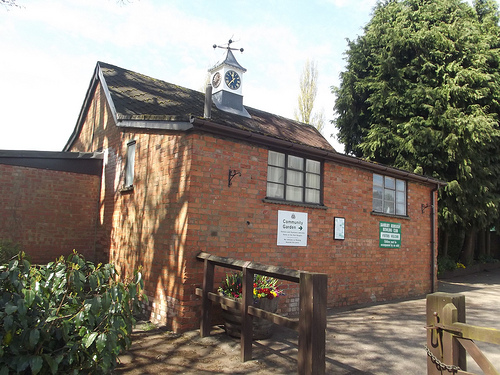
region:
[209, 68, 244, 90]
clock on two sides of tower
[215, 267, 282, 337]
bucket of red and yellow flowers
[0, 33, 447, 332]
a brick building with clock tower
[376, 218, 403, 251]
green and white sign on side of building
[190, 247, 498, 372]
an open wooden gate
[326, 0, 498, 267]
a large leaf covered tree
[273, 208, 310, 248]
a large white sign on side of building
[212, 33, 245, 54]
the weather vane on top of clock tower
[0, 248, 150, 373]
a large green bush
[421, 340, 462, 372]
a chain on the door of the fencec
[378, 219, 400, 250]
green sign with white writing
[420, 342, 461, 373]
chain around fence post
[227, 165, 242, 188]
metal hanger attached to building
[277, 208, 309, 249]
white sign with dark writing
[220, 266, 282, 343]
flowers in a large planter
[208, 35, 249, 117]
small clock tower on roof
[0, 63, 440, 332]
medium size red brick building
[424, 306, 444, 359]
locking mechanism for gate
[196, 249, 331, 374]
small dark wood fence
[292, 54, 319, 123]
top of tree with no leaves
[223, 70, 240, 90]
black clock with gold hands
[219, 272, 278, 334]
brown bucket with flowers in it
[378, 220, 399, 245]
green sign with white letters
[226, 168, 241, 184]
metal plant hanger on the wall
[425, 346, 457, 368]
chain on the fence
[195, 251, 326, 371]
small section of brown fencing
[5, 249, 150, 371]
bush with green leaves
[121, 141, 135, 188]
window on the side of the house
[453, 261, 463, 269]
yellow flowers in the garden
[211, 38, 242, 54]
black weathervane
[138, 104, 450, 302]
Small sized brick house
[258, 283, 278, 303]
Vase of colorful flowers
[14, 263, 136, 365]
Wide thick bushy shrub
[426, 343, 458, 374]
Chain on wooden gate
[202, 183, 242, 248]
Red colored brick wall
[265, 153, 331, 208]
Small wide high window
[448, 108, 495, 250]
Thick densely planted trees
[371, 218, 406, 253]
Green poster on brick wall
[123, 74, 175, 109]
Brown tiles on roof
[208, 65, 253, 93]
Watch on house chimney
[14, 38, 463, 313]
A brick building.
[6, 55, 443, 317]
A red brick building.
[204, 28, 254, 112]
A weather vain on the rooftop.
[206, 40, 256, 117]
A clock on the roof.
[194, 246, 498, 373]
A wooden fence.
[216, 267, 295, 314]
A flower box behind the fence.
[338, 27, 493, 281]
Trees beside the building.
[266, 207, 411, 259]
Signs are on the side of the building.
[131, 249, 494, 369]
The yard is dirt.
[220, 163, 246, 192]
A sign hanger on the side of the building.